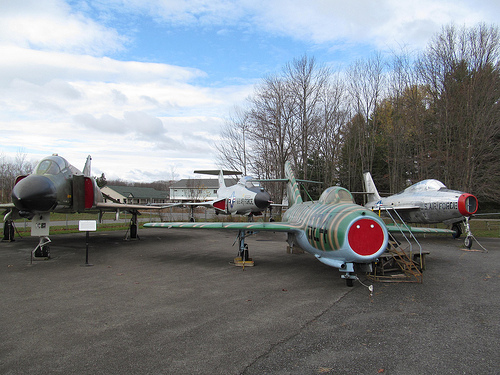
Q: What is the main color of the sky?
A: Blue.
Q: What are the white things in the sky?
A: Clouds.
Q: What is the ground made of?
A: Concrete.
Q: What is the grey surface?
A: The ground.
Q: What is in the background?
A: Trees.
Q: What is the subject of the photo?
A: Plane.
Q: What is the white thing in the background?
A: White.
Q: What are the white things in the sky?
A: Clouds.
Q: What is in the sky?
A: Clouds.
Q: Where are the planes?
A: On the tarmac.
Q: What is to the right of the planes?
A: Trees.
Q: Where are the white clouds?
A: In the sky.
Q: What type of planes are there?
A: Fighter jets.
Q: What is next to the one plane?
A: Stairs.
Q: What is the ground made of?
A: Asphalt.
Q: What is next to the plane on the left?
A: A sign.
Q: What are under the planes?
A: Wheels.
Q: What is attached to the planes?
A: Wings.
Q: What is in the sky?
A: Clouds.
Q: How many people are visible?
A: Zero.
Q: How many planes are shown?
A: Four.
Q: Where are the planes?
A: On the concrete.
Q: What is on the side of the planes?
A: The wings.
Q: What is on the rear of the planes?
A: The tail.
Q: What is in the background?
A: Buildings.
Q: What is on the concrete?
A: Four airplanes.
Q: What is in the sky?
A: Clouds.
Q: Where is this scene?
A: An airport.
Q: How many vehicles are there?
A: Four.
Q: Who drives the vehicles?
A: Pilots.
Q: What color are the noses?
A: Red.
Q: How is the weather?
A: It's sunny.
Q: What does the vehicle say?
A: U.S. Air Force.